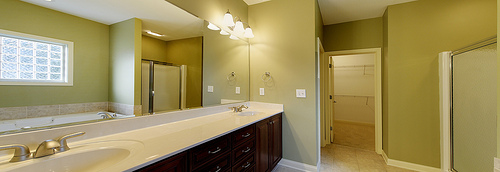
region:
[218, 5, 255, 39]
lights of the bathroom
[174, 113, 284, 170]
cabinets of the bathroom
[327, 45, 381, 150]
the doorway of the bathroom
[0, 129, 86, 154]
the sink faucet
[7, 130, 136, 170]
the sink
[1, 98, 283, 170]
the kitchen vanity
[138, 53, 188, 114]
the shower in the bathroom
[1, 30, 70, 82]
the window in the bathroom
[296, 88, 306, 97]
the light switch in the bathroom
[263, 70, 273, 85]
a towel rack in the bathroom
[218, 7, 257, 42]
row of three lamps on the wall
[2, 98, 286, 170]
a long white countertop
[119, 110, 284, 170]
a wooden countertop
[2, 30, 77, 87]
a frosted glass window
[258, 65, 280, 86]
an empty towel hanger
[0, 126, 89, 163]
a faucet over the sink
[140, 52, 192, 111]
a shower door reflected in the mirror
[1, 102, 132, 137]
reflection of a bathtub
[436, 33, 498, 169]
the corner of the shower door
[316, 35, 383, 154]
an empty closet with the door open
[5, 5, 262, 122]
The bathroom has a large mirror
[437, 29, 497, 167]
A shower glass door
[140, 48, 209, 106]
Reflection of a shower glass door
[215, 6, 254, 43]
Three lights are on the wall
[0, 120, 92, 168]
A faucet is on the counter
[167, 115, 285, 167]
The cabinets are made of wood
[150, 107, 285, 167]
The cabinets are a dark brown color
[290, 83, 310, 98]
Light switches are on the wall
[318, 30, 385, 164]
The doorway is open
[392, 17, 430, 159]
The wall is a light green color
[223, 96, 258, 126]
Sink with brushed aluminum handles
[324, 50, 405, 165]
large walk in closet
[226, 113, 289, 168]
three drawers in the cabinet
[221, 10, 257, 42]
three lights above the sink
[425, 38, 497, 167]
door to the shower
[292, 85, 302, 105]
light switch on the wall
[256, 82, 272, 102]
outlet on the wall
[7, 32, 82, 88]
mirror on the wall in the bathroom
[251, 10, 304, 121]
light green beige walls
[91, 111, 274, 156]
white cream colored counter